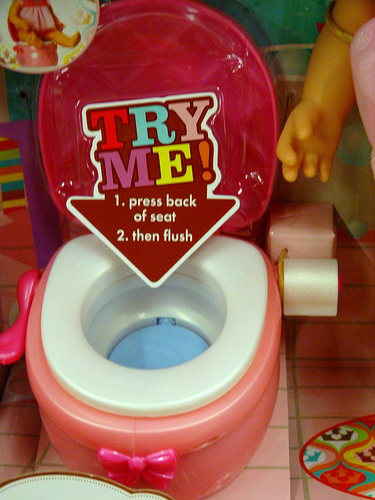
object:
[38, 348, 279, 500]
base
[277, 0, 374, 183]
arm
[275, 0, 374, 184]
doll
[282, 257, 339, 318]
tissue paper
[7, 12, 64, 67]
toilet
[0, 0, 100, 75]
picture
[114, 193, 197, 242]
lettering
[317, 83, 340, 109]
ground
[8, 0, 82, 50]
bear picture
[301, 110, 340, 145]
ground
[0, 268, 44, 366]
handle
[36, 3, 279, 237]
helmet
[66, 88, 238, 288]
arrow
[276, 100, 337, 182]
hand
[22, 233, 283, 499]
toilet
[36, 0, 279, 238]
toilet lid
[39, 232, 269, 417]
toilet seat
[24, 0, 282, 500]
basin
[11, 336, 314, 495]
shelf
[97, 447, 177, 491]
bow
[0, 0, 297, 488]
toilet